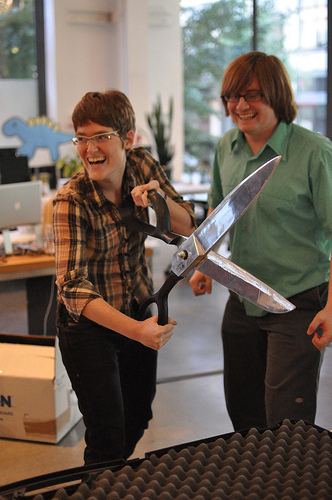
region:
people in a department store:
[52, 48, 318, 478]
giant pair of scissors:
[116, 154, 296, 320]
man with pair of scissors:
[197, 49, 327, 453]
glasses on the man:
[223, 87, 266, 102]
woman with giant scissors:
[50, 91, 178, 494]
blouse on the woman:
[59, 156, 187, 304]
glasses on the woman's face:
[72, 123, 126, 143]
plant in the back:
[145, 94, 183, 194]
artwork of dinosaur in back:
[0, 112, 74, 158]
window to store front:
[180, 5, 330, 289]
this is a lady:
[55, 96, 161, 354]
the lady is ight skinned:
[97, 303, 118, 332]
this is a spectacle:
[61, 133, 115, 141]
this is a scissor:
[152, 176, 258, 304]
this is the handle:
[149, 276, 176, 300]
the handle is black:
[157, 285, 166, 307]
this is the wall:
[79, 12, 144, 60]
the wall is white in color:
[79, 27, 132, 63]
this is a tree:
[192, 16, 210, 63]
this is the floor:
[173, 384, 201, 428]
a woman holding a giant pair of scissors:
[47, 92, 302, 326]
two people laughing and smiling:
[68, 50, 303, 194]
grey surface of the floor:
[179, 391, 204, 425]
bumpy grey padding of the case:
[228, 439, 296, 495]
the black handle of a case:
[1, 452, 120, 495]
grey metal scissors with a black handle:
[119, 155, 286, 334]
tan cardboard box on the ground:
[0, 324, 86, 446]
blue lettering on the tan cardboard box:
[0, 390, 19, 424]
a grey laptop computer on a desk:
[0, 172, 42, 231]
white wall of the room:
[138, 44, 173, 87]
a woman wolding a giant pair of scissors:
[49, 96, 284, 343]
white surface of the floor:
[170, 389, 219, 424]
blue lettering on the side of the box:
[0, 383, 18, 420]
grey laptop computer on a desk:
[0, 184, 45, 229]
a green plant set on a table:
[148, 99, 182, 191]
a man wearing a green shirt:
[191, 53, 329, 339]